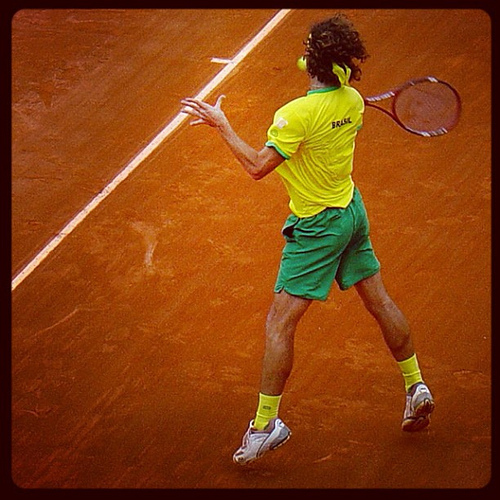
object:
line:
[148, 123, 163, 159]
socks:
[397, 354, 424, 395]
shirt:
[263, 86, 365, 219]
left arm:
[223, 102, 302, 180]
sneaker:
[232, 417, 292, 466]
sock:
[252, 395, 281, 428]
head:
[304, 13, 367, 90]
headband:
[333, 61, 353, 87]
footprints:
[55, 155, 465, 411]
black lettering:
[331, 115, 353, 129]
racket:
[364, 81, 460, 136]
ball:
[297, 55, 307, 71]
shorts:
[270, 187, 382, 303]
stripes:
[416, 127, 448, 137]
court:
[0, 0, 495, 499]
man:
[182, 17, 440, 466]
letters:
[329, 119, 340, 133]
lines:
[79, 184, 111, 212]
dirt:
[10, 130, 168, 292]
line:
[16, 168, 140, 288]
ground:
[57, 107, 230, 408]